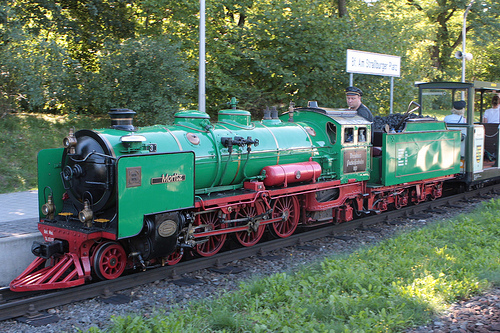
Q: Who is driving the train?
A: A man.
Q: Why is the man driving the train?
A: He is taking the people on a tour of the park.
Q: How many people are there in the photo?
A: Three.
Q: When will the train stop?
A: When the tour has ended.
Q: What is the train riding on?
A: Train tracks.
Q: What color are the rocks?
A: Gray.